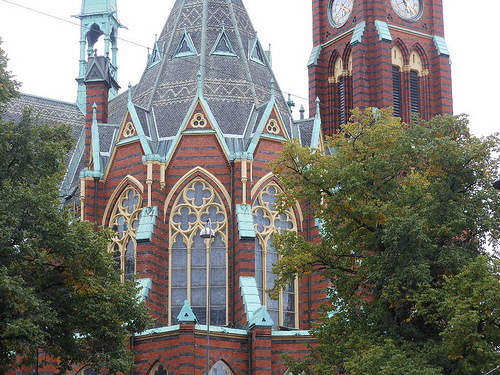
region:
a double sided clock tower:
[309, 0, 444, 51]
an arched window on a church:
[157, 165, 237, 335]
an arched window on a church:
[250, 169, 306, 331]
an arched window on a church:
[99, 174, 145, 331]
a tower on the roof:
[74, 0, 119, 123]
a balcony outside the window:
[132, 292, 247, 339]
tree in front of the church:
[269, 108, 495, 370]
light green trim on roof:
[163, 93, 233, 161]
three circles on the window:
[169, 180, 231, 235]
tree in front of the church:
[4, 94, 164, 374]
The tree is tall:
[327, 149, 498, 355]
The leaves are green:
[408, 233, 495, 347]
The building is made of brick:
[116, 208, 267, 365]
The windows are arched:
[120, 129, 253, 354]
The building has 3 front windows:
[75, 140, 326, 360]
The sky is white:
[205, 0, 366, 107]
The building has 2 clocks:
[321, 0, 451, 85]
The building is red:
[157, 301, 220, 369]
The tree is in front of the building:
[189, 136, 441, 373]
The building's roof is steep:
[55, 29, 376, 292]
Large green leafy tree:
[259, 105, 499, 374]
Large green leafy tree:
[1, 30, 164, 373]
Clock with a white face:
[388, 0, 423, 22]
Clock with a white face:
[328, 0, 355, 29]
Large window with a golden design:
[166, 175, 228, 323]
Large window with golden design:
[105, 185, 138, 284]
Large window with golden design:
[252, 182, 297, 329]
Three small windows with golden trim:
[266, 117, 279, 133]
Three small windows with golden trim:
[191, 111, 206, 128]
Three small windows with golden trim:
[123, 120, 134, 137]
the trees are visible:
[344, 199, 364, 255]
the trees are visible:
[346, 96, 427, 318]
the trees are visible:
[397, 217, 462, 371]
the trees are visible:
[351, 250, 416, 368]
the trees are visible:
[321, 197, 492, 368]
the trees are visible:
[369, 191, 444, 371]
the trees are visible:
[429, 231, 496, 330]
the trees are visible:
[439, 270, 493, 365]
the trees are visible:
[374, 126, 496, 336]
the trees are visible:
[359, 43, 402, 210]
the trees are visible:
[401, 128, 458, 323]